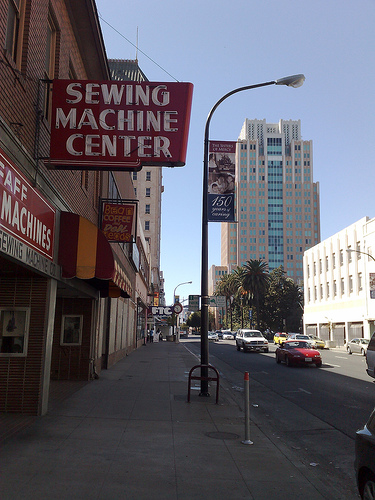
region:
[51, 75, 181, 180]
red and white sign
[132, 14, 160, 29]
white clouds in blue sky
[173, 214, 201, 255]
white clouds in blue sky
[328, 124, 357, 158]
white clouds in blue sky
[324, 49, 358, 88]
white clouds in blue sky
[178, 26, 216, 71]
white clouds in blue sky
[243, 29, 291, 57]
white clouds in blue sky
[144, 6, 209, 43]
white clouds in blue sky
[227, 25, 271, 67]
white clouds in blue sky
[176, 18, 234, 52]
white clouds in blue sky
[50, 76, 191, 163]
red "sweing machine center" sign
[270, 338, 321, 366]
red car on street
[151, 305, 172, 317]
sign in distance reading "FTC"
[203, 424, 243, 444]
manhole cover on sidewalk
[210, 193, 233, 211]
"150" on banner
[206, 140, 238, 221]
rectangular banner on pole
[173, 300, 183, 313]
red clock with white face in distance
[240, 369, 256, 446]
short pole with orange top sticking up from sidewalk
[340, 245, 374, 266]
top of street lamp in front of white building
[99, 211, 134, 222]
"coffee" in orange on red sign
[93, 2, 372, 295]
the sky is clear.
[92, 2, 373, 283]
the sky is blue.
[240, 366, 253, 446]
pole on the sidewalk.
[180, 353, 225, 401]
bike rack on the sidewalk.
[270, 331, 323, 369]
the car is red.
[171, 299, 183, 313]
clock in the distance.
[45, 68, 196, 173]
the sign is red.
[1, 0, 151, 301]
the building is brick.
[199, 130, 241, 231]
flag on the light post.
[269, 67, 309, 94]
the light is off.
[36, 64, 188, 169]
white and red sign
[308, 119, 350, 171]
white clouds in blue sky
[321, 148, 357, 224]
white clouds in blue sky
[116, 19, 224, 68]
white clouds in blue sky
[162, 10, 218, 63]
white clouds in blue sky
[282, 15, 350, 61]
white clouds in blue sky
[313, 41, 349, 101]
white clouds in blue sky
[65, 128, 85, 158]
The letter is white.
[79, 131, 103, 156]
The letter is white.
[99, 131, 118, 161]
The letter is white.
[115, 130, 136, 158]
The letter is white.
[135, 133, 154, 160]
The letter is white.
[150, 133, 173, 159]
The letter is white.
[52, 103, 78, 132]
The letter is white.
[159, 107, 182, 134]
The letter is white.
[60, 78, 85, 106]
The letter is white.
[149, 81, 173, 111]
The letter is white.